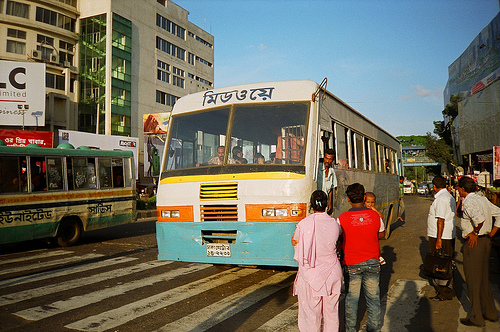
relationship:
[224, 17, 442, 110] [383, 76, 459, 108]
sky has clouds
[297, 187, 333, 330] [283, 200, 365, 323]
woman in pink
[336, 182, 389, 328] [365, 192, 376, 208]
man holding child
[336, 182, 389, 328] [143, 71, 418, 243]
man leaving bus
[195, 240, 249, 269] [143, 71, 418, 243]
plate on bus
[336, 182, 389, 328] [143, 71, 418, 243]
man driving bus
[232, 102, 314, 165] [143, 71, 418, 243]
window of bus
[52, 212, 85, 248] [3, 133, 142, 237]
tire of bus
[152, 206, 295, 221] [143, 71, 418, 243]
headlights of bus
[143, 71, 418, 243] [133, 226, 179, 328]
bus on street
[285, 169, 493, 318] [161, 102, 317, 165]
people see through windows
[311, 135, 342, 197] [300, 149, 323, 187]
man leaning out bus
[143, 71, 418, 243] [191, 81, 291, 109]
bus has letters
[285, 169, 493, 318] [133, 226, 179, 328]
people standing on street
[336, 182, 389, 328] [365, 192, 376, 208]
man holds child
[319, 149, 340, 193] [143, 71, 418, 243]
driver on bus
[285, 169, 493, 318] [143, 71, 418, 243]
people waiting for bus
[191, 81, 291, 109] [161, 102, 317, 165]
name of company on bus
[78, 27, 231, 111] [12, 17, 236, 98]
buildings in background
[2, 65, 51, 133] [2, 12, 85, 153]
advertisements on buildings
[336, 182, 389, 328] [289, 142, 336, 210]
man hanging on bus